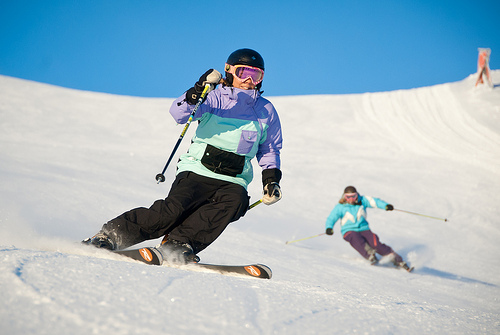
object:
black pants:
[97, 171, 249, 258]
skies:
[179, 261, 274, 280]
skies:
[108, 244, 165, 275]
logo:
[244, 262, 262, 278]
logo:
[137, 246, 153, 262]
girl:
[324, 184, 416, 273]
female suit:
[92, 46, 286, 270]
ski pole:
[244, 196, 263, 212]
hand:
[261, 181, 282, 206]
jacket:
[168, 83, 285, 189]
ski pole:
[282, 230, 328, 246]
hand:
[323, 227, 334, 237]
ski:
[106, 247, 170, 265]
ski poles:
[282, 189, 464, 256]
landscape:
[341, 110, 408, 145]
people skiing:
[84, 47, 283, 279]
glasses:
[224, 64, 262, 86]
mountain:
[0, 65, 498, 333]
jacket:
[326, 196, 386, 235]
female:
[82, 48, 285, 268]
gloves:
[260, 167, 284, 205]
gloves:
[185, 67, 222, 105]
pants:
[340, 230, 405, 268]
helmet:
[224, 47, 267, 92]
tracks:
[10, 237, 352, 332]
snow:
[5, 64, 491, 330]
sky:
[5, 2, 497, 85]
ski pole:
[391, 206, 450, 222]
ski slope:
[4, 61, 485, 328]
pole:
[153, 78, 213, 183]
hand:
[194, 68, 226, 94]